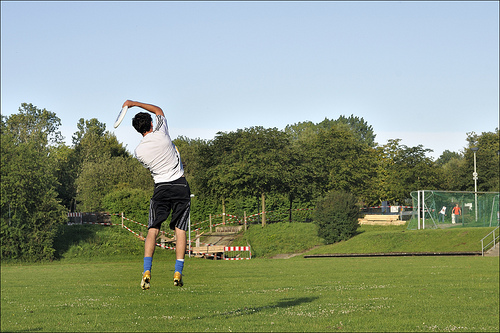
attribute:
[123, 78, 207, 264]
boy — black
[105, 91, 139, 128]
frisbee — white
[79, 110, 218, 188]
t shirt — white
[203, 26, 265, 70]
sky — blue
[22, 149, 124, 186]
trees — green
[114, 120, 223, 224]
man — jumping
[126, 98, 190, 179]
short — black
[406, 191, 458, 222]
net — green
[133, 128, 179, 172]
shirt — white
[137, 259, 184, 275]
socks — blue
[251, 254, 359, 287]
grass — green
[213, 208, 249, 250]
ribbons — red, white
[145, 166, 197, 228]
shorts — black